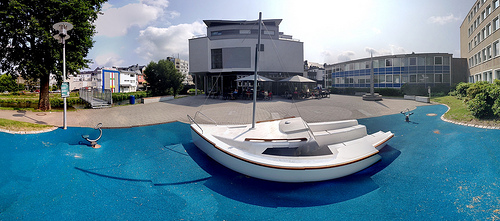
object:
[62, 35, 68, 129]
metal pole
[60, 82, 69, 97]
green sign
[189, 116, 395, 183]
boat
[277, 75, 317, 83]
parasol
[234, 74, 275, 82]
parasol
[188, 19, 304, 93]
building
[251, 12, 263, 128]
pole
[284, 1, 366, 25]
sun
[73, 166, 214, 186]
reflection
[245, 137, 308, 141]
railing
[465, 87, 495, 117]
green bush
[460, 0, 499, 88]
building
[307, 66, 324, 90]
building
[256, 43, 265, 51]
window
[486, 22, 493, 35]
window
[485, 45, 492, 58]
window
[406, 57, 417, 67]
window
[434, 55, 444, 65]
window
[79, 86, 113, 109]
bridge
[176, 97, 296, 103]
shadows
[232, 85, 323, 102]
seating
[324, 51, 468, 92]
building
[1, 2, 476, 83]
sky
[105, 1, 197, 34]
white clouds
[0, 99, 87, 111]
fence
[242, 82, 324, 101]
people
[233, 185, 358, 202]
shadow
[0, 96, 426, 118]
pavement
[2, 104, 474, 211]
creek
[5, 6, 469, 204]
outside